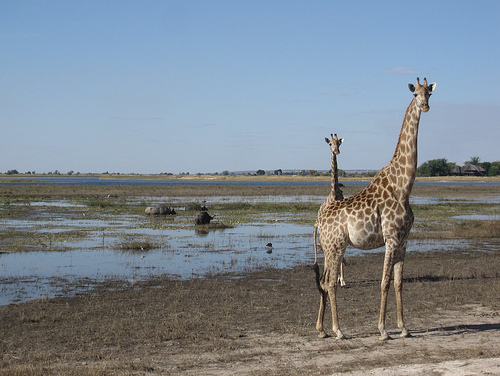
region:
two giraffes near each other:
[310, 75, 438, 342]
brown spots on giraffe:
[376, 178, 403, 212]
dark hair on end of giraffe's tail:
[311, 259, 329, 304]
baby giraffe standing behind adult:
[314, 129, 348, 289]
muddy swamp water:
[4, 223, 309, 293]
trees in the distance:
[1, 166, 328, 179]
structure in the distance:
[444, 160, 491, 177]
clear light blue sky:
[1, 0, 499, 168]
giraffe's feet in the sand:
[309, 320, 414, 342]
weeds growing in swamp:
[3, 193, 138, 257]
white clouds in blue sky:
[5, 6, 36, 67]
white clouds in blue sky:
[11, 47, 66, 109]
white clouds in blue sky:
[22, 105, 85, 172]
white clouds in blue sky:
[97, 6, 143, 69]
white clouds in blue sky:
[115, 84, 159, 148]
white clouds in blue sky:
[198, 25, 238, 113]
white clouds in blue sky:
[252, 31, 288, 132]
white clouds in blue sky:
[301, 31, 363, 105]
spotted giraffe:
[385, 77, 440, 302]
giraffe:
[307, 131, 349, 197]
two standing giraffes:
[311, 76, 434, 341]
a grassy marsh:
[1, 190, 496, 305]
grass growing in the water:
[1, 197, 499, 309]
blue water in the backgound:
[3, 176, 498, 186]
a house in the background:
[440, 158, 483, 178]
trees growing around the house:
[413, 155, 497, 178]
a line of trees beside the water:
[3, 168, 378, 178]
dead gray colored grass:
[15, 246, 492, 372]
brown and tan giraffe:
[311, 77, 437, 337]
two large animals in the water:
[142, 204, 217, 227]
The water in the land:
[21, 230, 223, 272]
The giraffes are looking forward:
[303, 76, 439, 343]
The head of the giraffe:
[316, 123, 350, 156]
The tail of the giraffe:
[306, 208, 328, 298]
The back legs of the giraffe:
[312, 250, 349, 340]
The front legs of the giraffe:
[368, 253, 418, 344]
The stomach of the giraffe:
[346, 190, 383, 249]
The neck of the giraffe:
[390, 110, 422, 186]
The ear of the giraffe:
[404, 79, 417, 96]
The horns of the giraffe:
[414, 68, 429, 90]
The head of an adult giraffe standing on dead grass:
[404, 78, 441, 115]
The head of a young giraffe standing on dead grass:
[322, 130, 349, 158]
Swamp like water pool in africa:
[0, 188, 284, 305]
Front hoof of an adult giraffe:
[375, 323, 391, 342]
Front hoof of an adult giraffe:
[397, 323, 417, 340]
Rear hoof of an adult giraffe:
[332, 330, 347, 341]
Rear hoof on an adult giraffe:
[312, 325, 330, 339]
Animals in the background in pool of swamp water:
[143, 201, 220, 226]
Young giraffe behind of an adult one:
[322, 133, 349, 197]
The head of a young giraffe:
[318, 134, 351, 159]